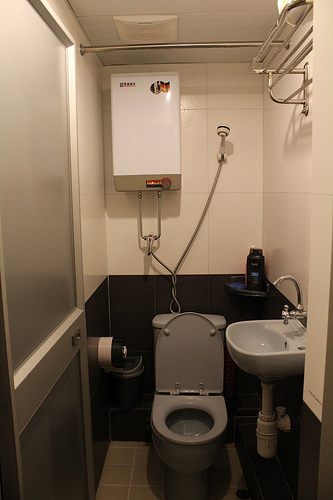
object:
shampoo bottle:
[243, 246, 266, 290]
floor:
[95, 437, 292, 498]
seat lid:
[152, 305, 227, 396]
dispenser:
[98, 335, 129, 370]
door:
[4, 6, 89, 492]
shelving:
[240, 0, 318, 128]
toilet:
[142, 297, 246, 499]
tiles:
[131, 449, 164, 489]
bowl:
[227, 321, 291, 356]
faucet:
[268, 270, 307, 328]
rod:
[77, 38, 294, 64]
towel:
[98, 330, 126, 372]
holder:
[95, 328, 134, 366]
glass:
[3, 0, 85, 376]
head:
[273, 269, 306, 323]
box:
[105, 66, 186, 193]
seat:
[150, 389, 230, 446]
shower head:
[215, 121, 232, 160]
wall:
[102, 59, 263, 439]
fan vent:
[112, 13, 179, 46]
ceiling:
[66, 0, 279, 67]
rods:
[266, 0, 315, 94]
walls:
[259, 0, 333, 496]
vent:
[112, 14, 180, 45]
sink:
[224, 313, 307, 388]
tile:
[101, 460, 134, 486]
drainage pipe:
[255, 387, 281, 461]